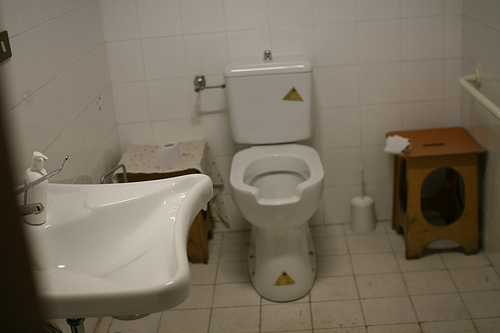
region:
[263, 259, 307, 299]
a caution sticker on the toilet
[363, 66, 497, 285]
a stool next to the toilet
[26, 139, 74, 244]
a soap dispenser on the bathroom sink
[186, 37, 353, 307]
a white porcelain toilet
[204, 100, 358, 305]
a toilet without a lid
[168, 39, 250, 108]
the pipe that connects the water to the toilet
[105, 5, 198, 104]
white tiling on the wall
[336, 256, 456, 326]
white bathroom floor tiling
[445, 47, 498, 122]
a handrail hanging on the window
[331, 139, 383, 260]
the toilet cleaner sitting on the floor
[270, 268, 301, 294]
yellow triangle sticker on a toilet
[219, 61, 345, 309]
toilet without a seat or lid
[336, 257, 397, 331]
dirty tile floor in bathroom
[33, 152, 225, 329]
sink attached to wall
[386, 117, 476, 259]
wooden stool in a bathroom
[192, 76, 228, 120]
roll of toilet paper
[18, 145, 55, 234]
liquid soap dispenser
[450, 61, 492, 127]
cream colored towel bar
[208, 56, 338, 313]
broken toilet with stickers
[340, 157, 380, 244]
white toilet bowl cleaner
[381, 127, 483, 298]
A stool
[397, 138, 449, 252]
A stool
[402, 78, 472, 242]
A stool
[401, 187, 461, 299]
A stool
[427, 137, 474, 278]
A stool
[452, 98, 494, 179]
A stool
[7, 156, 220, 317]
a white porcelain sink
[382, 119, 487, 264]
a brown wooden stool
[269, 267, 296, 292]
a yellow warning sticker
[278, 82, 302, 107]
a yellow warning sticker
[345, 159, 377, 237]
a toilet bowl cleaner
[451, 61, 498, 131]
a white handle grab bar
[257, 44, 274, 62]
a toilet flush button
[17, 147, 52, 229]
a bottle of hand soap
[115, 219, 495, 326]
a white tiled floor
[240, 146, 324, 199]
part of toilet bowl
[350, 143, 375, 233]
toilet brush holder on floor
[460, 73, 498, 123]
white rack in bathroom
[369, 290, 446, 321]
part of ceramic flooring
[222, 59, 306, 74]
lid on the toilet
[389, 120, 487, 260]
brown table in bathroom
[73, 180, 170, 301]
part of bathroom sink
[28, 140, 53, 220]
white plastic bottle on sink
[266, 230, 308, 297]
front base of toilet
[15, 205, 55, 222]
faucet on the sink